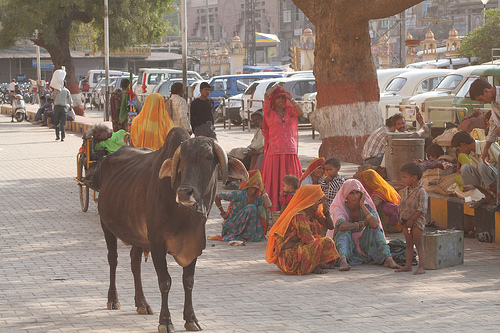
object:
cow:
[92, 125, 249, 333]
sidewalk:
[0, 105, 499, 332]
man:
[51, 79, 72, 141]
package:
[60, 107, 78, 121]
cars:
[400, 64, 497, 128]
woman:
[261, 87, 304, 210]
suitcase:
[416, 229, 464, 270]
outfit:
[261, 184, 341, 274]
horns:
[155, 126, 193, 149]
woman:
[328, 178, 402, 273]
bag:
[48, 64, 70, 92]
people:
[191, 83, 215, 139]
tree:
[291, 0, 427, 181]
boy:
[394, 161, 427, 273]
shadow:
[0, 175, 99, 330]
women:
[212, 169, 272, 244]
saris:
[340, 188, 362, 208]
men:
[449, 131, 499, 213]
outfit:
[258, 84, 303, 213]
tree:
[0, 0, 182, 117]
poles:
[103, 1, 111, 122]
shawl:
[265, 86, 302, 123]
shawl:
[264, 183, 328, 264]